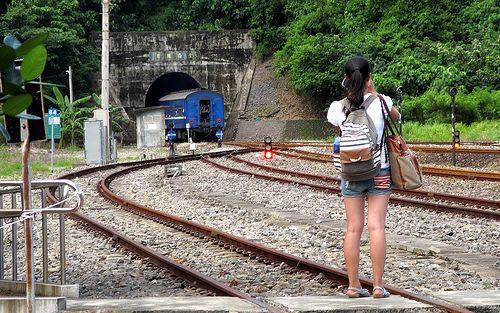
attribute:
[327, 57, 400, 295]
girl — standing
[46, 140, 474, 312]
track — train, rusted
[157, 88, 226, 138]
train — blue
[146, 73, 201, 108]
tunnel — concrete, black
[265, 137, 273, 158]
light — signal, on left, yellow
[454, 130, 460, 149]
light — signal, yellow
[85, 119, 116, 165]
box — gray, transformer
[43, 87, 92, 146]
tree — green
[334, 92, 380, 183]
backpack — brown, white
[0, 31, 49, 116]
leaves — green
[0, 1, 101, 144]
tree — tall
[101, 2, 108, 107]
pole — tall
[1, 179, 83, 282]
rail — silver, metal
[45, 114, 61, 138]
sign — green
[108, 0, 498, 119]
trees — green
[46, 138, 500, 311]
tracks — several